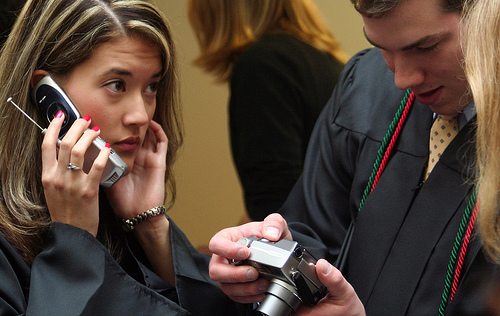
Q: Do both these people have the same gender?
A: No, they are both male and female.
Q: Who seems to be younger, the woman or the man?
A: The woman is younger than the man.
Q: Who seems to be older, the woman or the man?
A: The man is older than the woman.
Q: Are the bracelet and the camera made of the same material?
A: Yes, both the bracelet and the camera are made of metal.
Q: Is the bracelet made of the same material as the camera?
A: Yes, both the bracelet and the camera are made of metal.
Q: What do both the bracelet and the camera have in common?
A: The material, both the bracelet and the camera are metallic.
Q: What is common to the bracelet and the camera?
A: The material, both the bracelet and the camera are metallic.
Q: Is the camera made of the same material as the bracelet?
A: Yes, both the camera and the bracelet are made of metal.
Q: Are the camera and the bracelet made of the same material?
A: Yes, both the camera and the bracelet are made of metal.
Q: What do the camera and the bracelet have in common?
A: The material, both the camera and the bracelet are metallic.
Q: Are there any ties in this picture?
A: Yes, there is a tie.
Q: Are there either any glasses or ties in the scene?
A: Yes, there is a tie.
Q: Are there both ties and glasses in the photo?
A: No, there is a tie but no glasses.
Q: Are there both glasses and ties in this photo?
A: No, there is a tie but no glasses.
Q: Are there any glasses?
A: No, there are no glasses.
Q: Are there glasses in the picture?
A: No, there are no glasses.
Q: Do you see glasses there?
A: No, there are no glasses.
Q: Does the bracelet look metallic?
A: Yes, the bracelet is metallic.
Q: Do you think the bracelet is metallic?
A: Yes, the bracelet is metallic.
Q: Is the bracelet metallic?
A: Yes, the bracelet is metallic.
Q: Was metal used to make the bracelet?
A: Yes, the bracelet is made of metal.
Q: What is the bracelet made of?
A: The bracelet is made of metal.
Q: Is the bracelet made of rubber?
A: No, the bracelet is made of metal.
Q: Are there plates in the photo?
A: No, there are no plates.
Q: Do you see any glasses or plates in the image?
A: No, there are no plates or glasses.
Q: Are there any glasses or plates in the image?
A: No, there are no plates or glasses.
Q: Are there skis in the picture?
A: No, there are no skis.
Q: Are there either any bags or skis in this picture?
A: No, there are no skis or bags.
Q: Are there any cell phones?
A: Yes, there is a cell phone.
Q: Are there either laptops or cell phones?
A: Yes, there is a cell phone.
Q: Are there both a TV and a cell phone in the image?
A: No, there is a cell phone but no televisions.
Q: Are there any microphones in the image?
A: No, there are no microphones.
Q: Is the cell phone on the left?
A: Yes, the cell phone is on the left of the image.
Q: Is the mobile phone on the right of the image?
A: No, the mobile phone is on the left of the image.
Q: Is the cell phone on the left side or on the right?
A: The cell phone is on the left of the image.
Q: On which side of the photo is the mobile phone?
A: The mobile phone is on the left of the image.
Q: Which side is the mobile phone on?
A: The mobile phone is on the left of the image.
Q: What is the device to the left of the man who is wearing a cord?
A: The device is a cell phone.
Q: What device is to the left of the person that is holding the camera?
A: The device is a cell phone.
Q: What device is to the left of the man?
A: The device is a cell phone.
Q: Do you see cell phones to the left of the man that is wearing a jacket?
A: Yes, there is a cell phone to the left of the man.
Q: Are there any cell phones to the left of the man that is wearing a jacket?
A: Yes, there is a cell phone to the left of the man.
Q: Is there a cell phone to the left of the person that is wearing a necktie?
A: Yes, there is a cell phone to the left of the man.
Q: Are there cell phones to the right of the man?
A: No, the cell phone is to the left of the man.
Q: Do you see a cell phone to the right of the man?
A: No, the cell phone is to the left of the man.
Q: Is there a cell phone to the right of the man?
A: No, the cell phone is to the left of the man.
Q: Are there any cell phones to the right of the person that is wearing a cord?
A: No, the cell phone is to the left of the man.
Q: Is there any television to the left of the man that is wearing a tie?
A: No, there is a cell phone to the left of the man.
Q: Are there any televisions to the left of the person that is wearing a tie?
A: No, there is a cell phone to the left of the man.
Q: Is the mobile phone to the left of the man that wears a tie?
A: Yes, the mobile phone is to the left of the man.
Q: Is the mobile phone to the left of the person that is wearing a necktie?
A: Yes, the mobile phone is to the left of the man.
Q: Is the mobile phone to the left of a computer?
A: No, the mobile phone is to the left of the man.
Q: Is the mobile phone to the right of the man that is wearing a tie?
A: No, the mobile phone is to the left of the man.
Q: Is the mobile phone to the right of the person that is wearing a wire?
A: No, the mobile phone is to the left of the man.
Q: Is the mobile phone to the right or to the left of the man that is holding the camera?
A: The mobile phone is to the left of the man.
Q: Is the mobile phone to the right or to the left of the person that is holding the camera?
A: The mobile phone is to the left of the man.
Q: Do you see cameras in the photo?
A: Yes, there is a camera.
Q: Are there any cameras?
A: Yes, there is a camera.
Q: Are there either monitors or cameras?
A: Yes, there is a camera.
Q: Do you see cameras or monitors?
A: Yes, there is a camera.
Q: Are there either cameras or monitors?
A: Yes, there is a camera.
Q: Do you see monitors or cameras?
A: Yes, there is a camera.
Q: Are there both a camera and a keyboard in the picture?
A: No, there is a camera but no keyboards.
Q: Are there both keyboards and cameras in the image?
A: No, there is a camera but no keyboards.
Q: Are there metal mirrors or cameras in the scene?
A: Yes, there is a metal camera.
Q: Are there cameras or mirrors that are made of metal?
A: Yes, the camera is made of metal.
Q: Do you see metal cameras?
A: Yes, there is a metal camera.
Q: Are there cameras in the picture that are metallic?
A: Yes, there is a camera that is metallic.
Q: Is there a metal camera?
A: Yes, there is a camera that is made of metal.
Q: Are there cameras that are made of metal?
A: Yes, there is a camera that is made of metal.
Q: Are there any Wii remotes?
A: No, there are no Wii remotes.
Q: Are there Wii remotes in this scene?
A: No, there are no Wii remotes.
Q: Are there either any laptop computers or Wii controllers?
A: No, there are no Wii controllers or laptop computers.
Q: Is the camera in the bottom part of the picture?
A: Yes, the camera is in the bottom of the image.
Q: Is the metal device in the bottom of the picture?
A: Yes, the camera is in the bottom of the image.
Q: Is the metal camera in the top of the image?
A: No, the camera is in the bottom of the image.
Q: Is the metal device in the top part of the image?
A: No, the camera is in the bottom of the image.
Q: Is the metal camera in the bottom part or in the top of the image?
A: The camera is in the bottom of the image.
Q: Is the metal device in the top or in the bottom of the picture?
A: The camera is in the bottom of the image.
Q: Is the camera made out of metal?
A: Yes, the camera is made of metal.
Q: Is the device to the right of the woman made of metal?
A: Yes, the camera is made of metal.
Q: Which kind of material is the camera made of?
A: The camera is made of metal.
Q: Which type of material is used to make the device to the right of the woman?
A: The camera is made of metal.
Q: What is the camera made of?
A: The camera is made of metal.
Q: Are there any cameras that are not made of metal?
A: No, there is a camera but it is made of metal.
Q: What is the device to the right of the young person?
A: The device is a camera.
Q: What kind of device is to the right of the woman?
A: The device is a camera.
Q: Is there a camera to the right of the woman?
A: Yes, there is a camera to the right of the woman.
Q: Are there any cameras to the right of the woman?
A: Yes, there is a camera to the right of the woman.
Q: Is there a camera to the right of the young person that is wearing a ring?
A: Yes, there is a camera to the right of the woman.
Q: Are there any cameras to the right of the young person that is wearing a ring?
A: Yes, there is a camera to the right of the woman.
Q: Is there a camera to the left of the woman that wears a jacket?
A: No, the camera is to the right of the woman.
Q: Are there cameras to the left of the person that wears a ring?
A: No, the camera is to the right of the woman.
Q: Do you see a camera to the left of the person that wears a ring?
A: No, the camera is to the right of the woman.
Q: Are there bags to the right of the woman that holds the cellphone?
A: No, there is a camera to the right of the woman.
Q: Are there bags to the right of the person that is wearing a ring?
A: No, there is a camera to the right of the woman.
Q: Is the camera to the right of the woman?
A: Yes, the camera is to the right of the woman.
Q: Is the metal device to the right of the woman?
A: Yes, the camera is to the right of the woman.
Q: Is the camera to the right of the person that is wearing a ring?
A: Yes, the camera is to the right of the woman.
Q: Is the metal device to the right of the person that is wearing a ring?
A: Yes, the camera is to the right of the woman.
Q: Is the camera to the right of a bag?
A: No, the camera is to the right of the woman.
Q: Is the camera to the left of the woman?
A: No, the camera is to the right of the woman.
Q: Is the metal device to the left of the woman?
A: No, the camera is to the right of the woman.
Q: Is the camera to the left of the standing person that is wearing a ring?
A: No, the camera is to the right of the woman.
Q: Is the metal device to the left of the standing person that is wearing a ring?
A: No, the camera is to the right of the woman.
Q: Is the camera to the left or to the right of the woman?
A: The camera is to the right of the woman.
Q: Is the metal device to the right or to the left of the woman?
A: The camera is to the right of the woman.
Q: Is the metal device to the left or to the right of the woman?
A: The camera is to the right of the woman.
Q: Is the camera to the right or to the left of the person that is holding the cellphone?
A: The camera is to the right of the woman.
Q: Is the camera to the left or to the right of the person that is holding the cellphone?
A: The camera is to the right of the woman.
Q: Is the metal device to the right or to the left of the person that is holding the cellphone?
A: The camera is to the right of the woman.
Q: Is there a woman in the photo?
A: Yes, there is a woman.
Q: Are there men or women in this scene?
A: Yes, there is a woman.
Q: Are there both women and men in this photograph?
A: Yes, there are both a woman and a man.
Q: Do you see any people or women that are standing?
A: Yes, the woman is standing.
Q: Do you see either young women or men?
A: Yes, there is a young woman.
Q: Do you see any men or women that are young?
A: Yes, the woman is young.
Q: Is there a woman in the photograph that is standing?
A: Yes, there is a woman that is standing.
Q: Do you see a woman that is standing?
A: Yes, there is a woman that is standing.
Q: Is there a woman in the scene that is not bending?
A: Yes, there is a woman that is standing.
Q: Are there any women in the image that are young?
A: Yes, there is a young woman.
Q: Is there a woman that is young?
A: Yes, there is a woman that is young.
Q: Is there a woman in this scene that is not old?
A: Yes, there is an young woman.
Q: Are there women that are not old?
A: Yes, there is an young woman.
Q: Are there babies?
A: No, there are no babies.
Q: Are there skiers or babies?
A: No, there are no babies or skiers.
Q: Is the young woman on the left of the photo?
A: Yes, the woman is on the left of the image.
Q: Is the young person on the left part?
A: Yes, the woman is on the left of the image.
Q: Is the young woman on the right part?
A: No, the woman is on the left of the image.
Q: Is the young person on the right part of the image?
A: No, the woman is on the left of the image.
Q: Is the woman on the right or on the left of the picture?
A: The woman is on the left of the image.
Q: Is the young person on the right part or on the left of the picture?
A: The woman is on the left of the image.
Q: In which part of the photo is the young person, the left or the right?
A: The woman is on the left of the image.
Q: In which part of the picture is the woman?
A: The woman is on the left of the image.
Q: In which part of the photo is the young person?
A: The woman is on the left of the image.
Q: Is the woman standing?
A: Yes, the woman is standing.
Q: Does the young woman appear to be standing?
A: Yes, the woman is standing.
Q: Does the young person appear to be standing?
A: Yes, the woman is standing.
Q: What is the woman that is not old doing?
A: The woman is standing.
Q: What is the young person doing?
A: The woman is standing.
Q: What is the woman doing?
A: The woman is standing.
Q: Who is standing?
A: The woman is standing.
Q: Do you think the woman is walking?
A: No, the woman is standing.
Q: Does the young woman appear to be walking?
A: No, the woman is standing.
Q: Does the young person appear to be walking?
A: No, the woman is standing.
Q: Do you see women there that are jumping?
A: No, there is a woman but she is standing.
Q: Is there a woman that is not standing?
A: No, there is a woman but she is standing.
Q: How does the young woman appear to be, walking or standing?
A: The woman is standing.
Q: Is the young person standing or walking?
A: The woman is standing.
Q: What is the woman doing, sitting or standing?
A: The woman is standing.